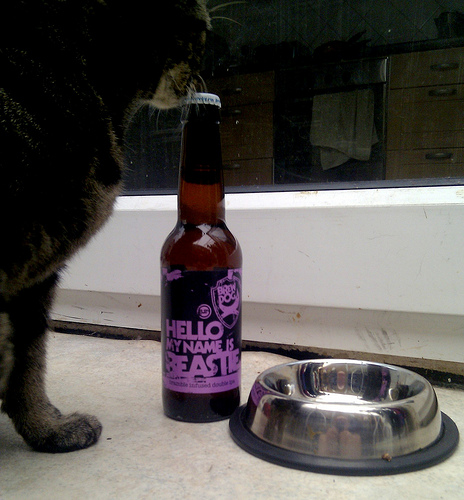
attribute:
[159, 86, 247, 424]
beer bottle — on table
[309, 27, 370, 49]
pans reflection — in window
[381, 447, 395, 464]
crumb — cat food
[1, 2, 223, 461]
curious cat — sniffing lid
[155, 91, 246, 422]
brown bottle — with purple writing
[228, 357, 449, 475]
food bowl — black and silver, empty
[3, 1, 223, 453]
black cat — with wiskers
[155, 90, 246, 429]
bottle — dog brew, beer, dark brown, brown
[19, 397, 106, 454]
paw — gray, brown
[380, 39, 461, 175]
dresser — wooden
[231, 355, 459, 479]
bowl — silver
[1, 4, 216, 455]
cat — sniffing a beer, gray, black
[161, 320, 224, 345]
word — hello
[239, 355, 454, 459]
bowl — round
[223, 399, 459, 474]
base — rubber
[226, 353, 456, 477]
dish — silver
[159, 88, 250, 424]
bottle — brown glass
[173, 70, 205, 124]
whiskers — white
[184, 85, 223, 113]
cap — grey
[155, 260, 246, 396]
label — purple, black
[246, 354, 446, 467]
dish — silver, cat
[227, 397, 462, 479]
ring — black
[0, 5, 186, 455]
cat — black, brown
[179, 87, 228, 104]
cap — bottle 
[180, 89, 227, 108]
cap — grey 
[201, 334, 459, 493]
dish — feeding dish, silver, black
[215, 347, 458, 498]
cat dish — silver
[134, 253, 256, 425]
labeling — purple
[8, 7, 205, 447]
cat — standing, sniffing, grey, brown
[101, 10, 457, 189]
pane — glass pane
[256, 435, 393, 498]
rim — black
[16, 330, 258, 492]
carpeting — beige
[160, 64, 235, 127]
cap — silver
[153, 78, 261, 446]
bottle — brown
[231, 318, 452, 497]
food bowl — silver, black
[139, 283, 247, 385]
label — black, purple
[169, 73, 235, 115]
cap — silver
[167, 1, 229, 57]
nose — cat's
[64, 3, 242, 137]
face — cat's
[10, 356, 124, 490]
leg — front leg, cat's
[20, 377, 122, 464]
paw — cat's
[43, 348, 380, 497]
flooring — white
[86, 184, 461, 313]
baseboard — white, wooden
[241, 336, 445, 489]
bowl — silver